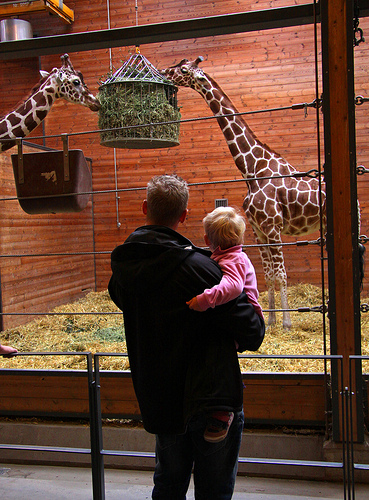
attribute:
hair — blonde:
[144, 174, 189, 228]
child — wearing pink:
[207, 186, 270, 285]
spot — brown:
[204, 90, 214, 101]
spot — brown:
[228, 142, 239, 156]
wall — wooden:
[0, 0, 367, 298]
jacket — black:
[107, 219, 269, 437]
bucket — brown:
[9, 147, 98, 214]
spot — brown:
[264, 165, 285, 187]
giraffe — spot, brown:
[159, 53, 360, 330]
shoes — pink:
[192, 381, 264, 448]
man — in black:
[106, 174, 265, 498]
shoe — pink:
[202, 410, 233, 441]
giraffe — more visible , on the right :
[126, 28, 341, 253]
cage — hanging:
[93, 49, 182, 145]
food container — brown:
[8, 136, 93, 215]